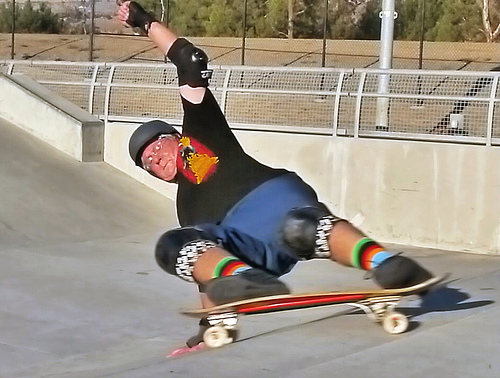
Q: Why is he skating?
A: Fun.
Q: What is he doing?
A: Skating.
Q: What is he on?
A: Skateboard.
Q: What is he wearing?
A: Helmet.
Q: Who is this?
A: Man.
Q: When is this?
A: Daytime.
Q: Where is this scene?
A: At a skatepark.